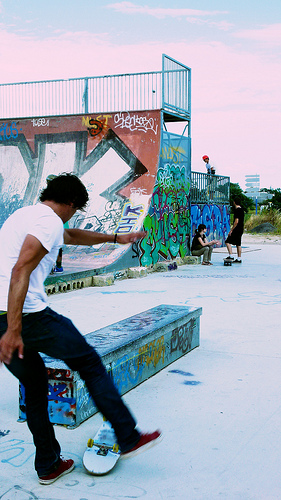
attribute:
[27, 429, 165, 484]
sneakers — white, red, black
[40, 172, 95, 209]
hair — dark, black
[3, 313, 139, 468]
jeans — blue, green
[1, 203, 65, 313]
shirt — white, black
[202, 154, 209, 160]
helmet — red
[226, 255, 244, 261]
socks — white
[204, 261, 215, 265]
woman — wearing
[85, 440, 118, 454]
wheel — yellow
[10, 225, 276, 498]
ground — paint